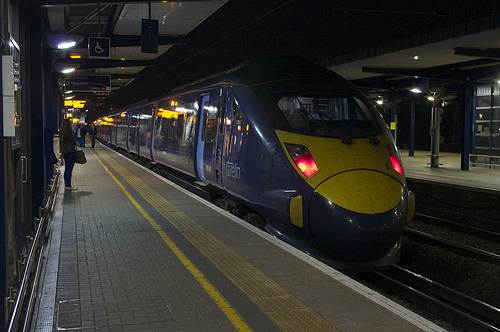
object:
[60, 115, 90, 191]
woman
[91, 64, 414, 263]
train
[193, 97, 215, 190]
side door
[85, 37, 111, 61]
handicapped sign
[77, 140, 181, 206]
sidewalk area is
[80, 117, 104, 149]
people cross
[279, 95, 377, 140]
front windshield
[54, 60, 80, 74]
lights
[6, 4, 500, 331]
station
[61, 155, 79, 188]
jeans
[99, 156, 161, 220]
yellow stripes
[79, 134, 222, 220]
sidewalk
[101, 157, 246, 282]
yellow lines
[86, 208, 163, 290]
pavement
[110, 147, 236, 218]
white line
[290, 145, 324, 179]
headlight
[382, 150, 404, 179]
headlight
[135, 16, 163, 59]
sign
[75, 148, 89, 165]
purse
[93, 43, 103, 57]
wheelchair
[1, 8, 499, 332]
scene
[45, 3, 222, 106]
ceiling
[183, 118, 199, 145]
man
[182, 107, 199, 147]
window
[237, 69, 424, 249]
train front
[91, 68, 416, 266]
whole train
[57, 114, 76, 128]
brown hair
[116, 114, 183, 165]
reflection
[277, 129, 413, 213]
front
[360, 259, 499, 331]
track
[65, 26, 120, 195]
handicapped area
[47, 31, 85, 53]
overhead lights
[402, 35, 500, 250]
opposite side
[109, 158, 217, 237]
safety